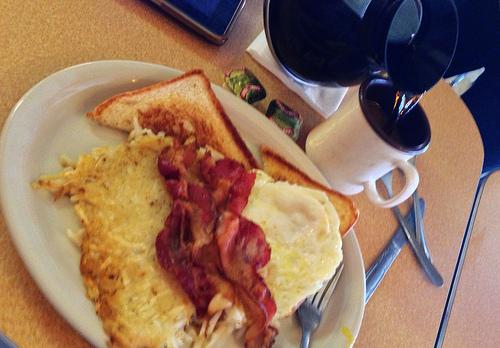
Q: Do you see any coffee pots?
A: Yes, there is a coffee pot.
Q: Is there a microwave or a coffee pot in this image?
A: Yes, there is a coffee pot.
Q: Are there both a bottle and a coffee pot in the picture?
A: No, there is a coffee pot but no bottles.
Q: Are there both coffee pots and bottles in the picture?
A: No, there is a coffee pot but no bottles.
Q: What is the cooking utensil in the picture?
A: The cooking utensil is a coffee pot.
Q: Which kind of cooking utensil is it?
A: The cooking utensil is a coffee pot.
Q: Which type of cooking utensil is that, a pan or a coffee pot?
A: That is a coffee pot.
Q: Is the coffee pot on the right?
A: Yes, the coffee pot is on the right of the image.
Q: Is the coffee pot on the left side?
A: No, the coffee pot is on the right of the image.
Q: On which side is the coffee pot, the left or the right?
A: The coffee pot is on the right of the image.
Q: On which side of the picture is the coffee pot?
A: The coffee pot is on the right of the image.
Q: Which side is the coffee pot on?
A: The coffee pot is on the right of the image.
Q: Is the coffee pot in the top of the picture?
A: Yes, the coffee pot is in the top of the image.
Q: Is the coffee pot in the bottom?
A: No, the coffee pot is in the top of the image.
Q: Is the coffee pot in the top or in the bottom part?
A: The coffee pot is in the top of the image.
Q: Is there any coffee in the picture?
A: Yes, there is coffee.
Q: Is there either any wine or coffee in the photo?
A: Yes, there is coffee.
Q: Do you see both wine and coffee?
A: No, there is coffee but no wine.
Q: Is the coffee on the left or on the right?
A: The coffee is on the right of the image.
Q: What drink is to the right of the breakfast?
A: The drink is coffee.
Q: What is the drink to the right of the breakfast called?
A: The drink is coffee.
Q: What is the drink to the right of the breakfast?
A: The drink is coffee.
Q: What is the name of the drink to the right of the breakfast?
A: The drink is coffee.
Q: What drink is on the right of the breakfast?
A: The drink is coffee.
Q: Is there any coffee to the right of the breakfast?
A: Yes, there is coffee to the right of the breakfast.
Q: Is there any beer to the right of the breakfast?
A: No, there is coffee to the right of the breakfast.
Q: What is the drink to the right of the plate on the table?
A: The drink is coffee.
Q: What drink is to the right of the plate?
A: The drink is coffee.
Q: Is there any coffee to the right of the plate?
A: Yes, there is coffee to the right of the plate.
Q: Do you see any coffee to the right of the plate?
A: Yes, there is coffee to the right of the plate.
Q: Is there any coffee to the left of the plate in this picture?
A: No, the coffee is to the right of the plate.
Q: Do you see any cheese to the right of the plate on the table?
A: No, there is coffee to the right of the plate.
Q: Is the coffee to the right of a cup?
A: No, the coffee is to the right of a plate.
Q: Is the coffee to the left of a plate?
A: No, the coffee is to the right of a plate.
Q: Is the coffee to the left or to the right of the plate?
A: The coffee is to the right of the plate.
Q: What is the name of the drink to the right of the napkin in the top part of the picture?
A: The drink is coffee.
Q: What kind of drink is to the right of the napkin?
A: The drink is coffee.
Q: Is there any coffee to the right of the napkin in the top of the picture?
A: Yes, there is coffee to the right of the napkin.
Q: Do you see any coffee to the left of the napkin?
A: No, the coffee is to the right of the napkin.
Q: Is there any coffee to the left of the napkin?
A: No, the coffee is to the right of the napkin.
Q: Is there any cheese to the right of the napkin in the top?
A: No, there is coffee to the right of the napkin.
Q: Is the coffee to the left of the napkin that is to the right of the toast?
A: No, the coffee is to the right of the napkin.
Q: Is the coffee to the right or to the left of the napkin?
A: The coffee is to the right of the napkin.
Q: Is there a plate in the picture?
A: Yes, there is a plate.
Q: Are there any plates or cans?
A: Yes, there is a plate.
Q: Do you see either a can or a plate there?
A: Yes, there is a plate.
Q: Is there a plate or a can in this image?
A: Yes, there is a plate.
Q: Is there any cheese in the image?
A: No, there is no cheese.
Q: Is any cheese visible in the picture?
A: No, there is no cheese.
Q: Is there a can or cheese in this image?
A: No, there are no cheese or cans.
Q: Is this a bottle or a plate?
A: This is a plate.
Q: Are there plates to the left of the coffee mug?
A: Yes, there is a plate to the left of the coffee mug.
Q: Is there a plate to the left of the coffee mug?
A: Yes, there is a plate to the left of the coffee mug.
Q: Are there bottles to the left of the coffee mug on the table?
A: No, there is a plate to the left of the coffee mug.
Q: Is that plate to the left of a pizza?
A: No, the plate is to the left of a coffee mug.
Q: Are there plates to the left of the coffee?
A: Yes, there is a plate to the left of the coffee.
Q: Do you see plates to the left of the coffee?
A: Yes, there is a plate to the left of the coffee.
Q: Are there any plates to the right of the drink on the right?
A: No, the plate is to the left of the coffee.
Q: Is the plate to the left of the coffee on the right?
A: Yes, the plate is to the left of the coffee.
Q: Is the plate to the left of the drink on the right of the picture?
A: Yes, the plate is to the left of the coffee.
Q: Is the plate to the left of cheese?
A: No, the plate is to the left of the coffee.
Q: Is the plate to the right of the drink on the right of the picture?
A: No, the plate is to the left of the coffee.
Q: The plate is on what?
A: The plate is on the table.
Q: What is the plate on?
A: The plate is on the table.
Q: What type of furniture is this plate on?
A: The plate is on the table.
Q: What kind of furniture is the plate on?
A: The plate is on the table.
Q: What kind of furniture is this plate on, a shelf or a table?
A: The plate is on a table.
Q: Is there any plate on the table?
A: Yes, there is a plate on the table.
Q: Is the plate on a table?
A: Yes, the plate is on a table.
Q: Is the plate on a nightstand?
A: No, the plate is on a table.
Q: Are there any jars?
A: No, there are no jars.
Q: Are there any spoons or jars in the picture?
A: No, there are no jars or spoons.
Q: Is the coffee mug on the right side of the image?
A: Yes, the coffee mug is on the right of the image.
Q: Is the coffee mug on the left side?
A: No, the coffee mug is on the right of the image.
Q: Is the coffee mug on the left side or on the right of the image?
A: The coffee mug is on the right of the image.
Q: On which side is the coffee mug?
A: The coffee mug is on the right of the image.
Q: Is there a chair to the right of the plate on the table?
A: No, there is a coffee mug to the right of the plate.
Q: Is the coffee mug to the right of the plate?
A: Yes, the coffee mug is to the right of the plate.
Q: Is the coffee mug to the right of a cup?
A: No, the coffee mug is to the right of the plate.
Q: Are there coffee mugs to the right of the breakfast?
A: Yes, there is a coffee mug to the right of the breakfast.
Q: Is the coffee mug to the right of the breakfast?
A: Yes, the coffee mug is to the right of the breakfast.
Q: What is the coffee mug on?
A: The coffee mug is on the table.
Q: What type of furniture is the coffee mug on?
A: The coffee mug is on the table.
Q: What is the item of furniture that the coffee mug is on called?
A: The piece of furniture is a table.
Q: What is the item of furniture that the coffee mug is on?
A: The piece of furniture is a table.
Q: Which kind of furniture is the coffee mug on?
A: The coffee mug is on the table.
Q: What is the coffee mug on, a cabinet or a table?
A: The coffee mug is on a table.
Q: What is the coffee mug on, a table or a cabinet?
A: The coffee mug is on a table.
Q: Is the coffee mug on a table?
A: Yes, the coffee mug is on a table.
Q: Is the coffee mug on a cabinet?
A: No, the coffee mug is on a table.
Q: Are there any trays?
A: No, there are no trays.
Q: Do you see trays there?
A: No, there are no trays.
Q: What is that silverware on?
A: The silverware is on the table.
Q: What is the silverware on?
A: The silverware is on the table.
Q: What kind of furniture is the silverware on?
A: The silverware is on the table.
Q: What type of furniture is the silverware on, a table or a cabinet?
A: The silverware is on a table.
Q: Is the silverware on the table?
A: Yes, the silverware is on the table.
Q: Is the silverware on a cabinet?
A: No, the silverware is on the table.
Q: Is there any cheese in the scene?
A: No, there is no cheese.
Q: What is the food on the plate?
A: The food is an egg.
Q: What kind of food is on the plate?
A: The food is an egg.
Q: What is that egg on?
A: The egg is on the plate.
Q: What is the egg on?
A: The egg is on the plate.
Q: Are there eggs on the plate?
A: Yes, there is an egg on the plate.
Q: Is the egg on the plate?
A: Yes, the egg is on the plate.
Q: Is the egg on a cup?
A: No, the egg is on the plate.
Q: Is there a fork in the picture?
A: Yes, there is a fork.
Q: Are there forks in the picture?
A: Yes, there is a fork.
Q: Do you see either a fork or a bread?
A: Yes, there is a fork.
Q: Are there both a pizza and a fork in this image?
A: No, there is a fork but no pizzas.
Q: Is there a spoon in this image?
A: No, there are no spoons.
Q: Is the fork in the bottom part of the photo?
A: Yes, the fork is in the bottom of the image.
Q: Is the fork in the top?
A: No, the fork is in the bottom of the image.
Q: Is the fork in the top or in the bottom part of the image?
A: The fork is in the bottom of the image.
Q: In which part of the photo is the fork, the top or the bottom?
A: The fork is in the bottom of the image.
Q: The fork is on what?
A: The fork is on the plate.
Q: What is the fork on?
A: The fork is on the plate.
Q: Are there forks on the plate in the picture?
A: Yes, there is a fork on the plate.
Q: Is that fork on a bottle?
A: No, the fork is on the plate.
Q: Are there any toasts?
A: Yes, there is a toast.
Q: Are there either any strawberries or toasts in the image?
A: Yes, there is a toast.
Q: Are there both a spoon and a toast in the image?
A: No, there is a toast but no spoons.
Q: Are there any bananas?
A: No, there are no bananas.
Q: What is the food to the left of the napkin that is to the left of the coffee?
A: The food is a toast.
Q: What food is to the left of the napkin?
A: The food is a toast.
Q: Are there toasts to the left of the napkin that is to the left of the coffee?
A: Yes, there is a toast to the left of the napkin.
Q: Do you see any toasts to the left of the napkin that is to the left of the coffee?
A: Yes, there is a toast to the left of the napkin.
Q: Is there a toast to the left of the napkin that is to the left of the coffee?
A: Yes, there is a toast to the left of the napkin.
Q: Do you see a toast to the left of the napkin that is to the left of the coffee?
A: Yes, there is a toast to the left of the napkin.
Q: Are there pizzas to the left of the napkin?
A: No, there is a toast to the left of the napkin.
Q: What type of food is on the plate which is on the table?
A: The food is a toast.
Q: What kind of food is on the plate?
A: The food is a toast.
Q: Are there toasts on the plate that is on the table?
A: Yes, there is a toast on the plate.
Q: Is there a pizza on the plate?
A: No, there is a toast on the plate.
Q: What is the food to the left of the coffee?
A: The food is a toast.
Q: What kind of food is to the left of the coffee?
A: The food is a toast.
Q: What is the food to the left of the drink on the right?
A: The food is a toast.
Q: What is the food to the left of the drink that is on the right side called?
A: The food is a toast.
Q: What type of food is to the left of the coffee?
A: The food is a toast.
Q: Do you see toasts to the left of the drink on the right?
A: Yes, there is a toast to the left of the coffee.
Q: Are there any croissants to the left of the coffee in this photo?
A: No, there is a toast to the left of the coffee.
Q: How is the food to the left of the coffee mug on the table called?
A: The food is a toast.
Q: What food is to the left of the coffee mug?
A: The food is a toast.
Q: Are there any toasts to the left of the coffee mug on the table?
A: Yes, there is a toast to the left of the coffee mug.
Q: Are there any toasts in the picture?
A: Yes, there is a toast.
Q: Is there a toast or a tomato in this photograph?
A: Yes, there is a toast.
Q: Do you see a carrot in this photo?
A: No, there are no carrots.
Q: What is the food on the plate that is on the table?
A: The food is a toast.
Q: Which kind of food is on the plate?
A: The food is a toast.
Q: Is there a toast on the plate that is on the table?
A: Yes, there is a toast on the plate.